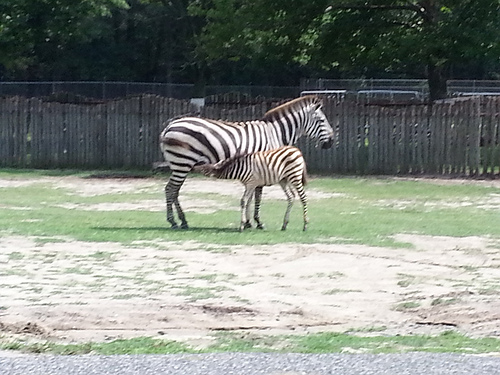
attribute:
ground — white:
[446, 137, 457, 148]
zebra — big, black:
[157, 92, 337, 227]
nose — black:
[321, 133, 334, 149]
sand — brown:
[158, 245, 484, 327]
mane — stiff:
[266, 95, 316, 121]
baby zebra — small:
[192, 128, 418, 257]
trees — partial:
[42, 10, 483, 90]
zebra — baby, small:
[188, 142, 312, 234]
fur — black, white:
[160, 99, 327, 225]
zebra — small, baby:
[201, 147, 310, 232]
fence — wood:
[3, 90, 484, 179]